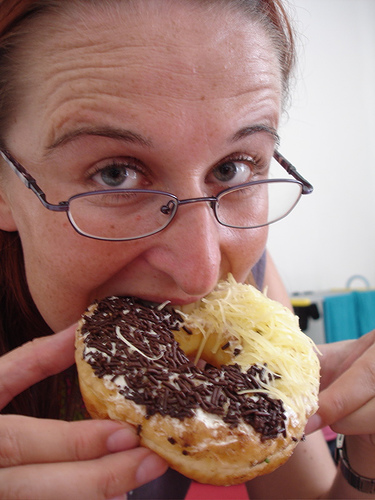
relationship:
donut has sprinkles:
[78, 296, 321, 488] [102, 323, 172, 385]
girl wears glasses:
[8, 1, 286, 315] [43, 182, 310, 240]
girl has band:
[8, 1, 286, 315] [335, 434, 374, 499]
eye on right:
[211, 156, 260, 187] [195, 1, 373, 482]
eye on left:
[84, 158, 152, 193] [1, 2, 197, 402]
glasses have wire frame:
[43, 182, 310, 240] [2, 148, 66, 212]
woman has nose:
[8, 1, 286, 315] [149, 176, 219, 292]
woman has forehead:
[8, 1, 286, 315] [39, 9, 280, 116]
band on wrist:
[335, 434, 374, 499] [346, 435, 375, 478]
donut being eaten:
[78, 296, 321, 488] [118, 291, 238, 314]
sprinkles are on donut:
[102, 323, 172, 385] [78, 296, 321, 488]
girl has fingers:
[0, 1, 375, 500] [2, 412, 169, 499]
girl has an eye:
[0, 1, 375, 500] [84, 158, 152, 193]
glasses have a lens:
[43, 182, 310, 240] [72, 199, 170, 224]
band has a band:
[335, 434, 374, 499] [335, 434, 374, 499]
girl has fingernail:
[0, 1, 375, 500] [110, 431, 139, 448]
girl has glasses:
[0, 1, 375, 500] [43, 182, 310, 240]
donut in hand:
[78, 296, 321, 488] [321, 330, 374, 435]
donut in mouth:
[78, 296, 321, 488] [113, 293, 231, 307]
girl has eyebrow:
[0, 1, 375, 500] [50, 128, 142, 145]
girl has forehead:
[0, 1, 375, 500] [39, 9, 280, 116]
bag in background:
[324, 293, 375, 331] [299, 205, 374, 334]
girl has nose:
[0, 1, 375, 500] [149, 176, 219, 292]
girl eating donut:
[0, 1, 375, 500] [78, 296, 321, 488]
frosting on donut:
[234, 306, 294, 355] [78, 296, 321, 488]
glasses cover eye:
[43, 182, 310, 240] [84, 158, 152, 193]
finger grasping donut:
[1, 413, 141, 449] [78, 296, 321, 488]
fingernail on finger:
[110, 431, 139, 448] [1, 413, 141, 449]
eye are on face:
[84, 158, 152, 193] [39, 1, 270, 302]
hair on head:
[234, 1, 291, 98] [6, 2, 286, 327]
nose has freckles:
[149, 176, 219, 292] [178, 219, 201, 231]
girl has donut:
[0, 1, 375, 500] [78, 296, 321, 488]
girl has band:
[0, 1, 375, 500] [335, 434, 374, 499]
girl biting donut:
[0, 1, 375, 500] [78, 296, 321, 488]